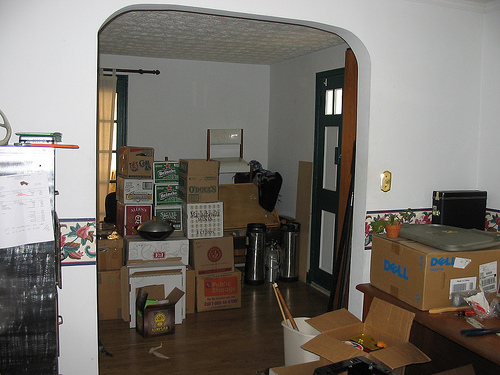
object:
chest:
[429, 188, 488, 232]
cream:
[277, 316, 323, 368]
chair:
[203, 127, 252, 174]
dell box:
[366, 232, 498, 313]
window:
[96, 151, 118, 184]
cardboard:
[114, 147, 130, 180]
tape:
[146, 340, 169, 361]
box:
[124, 234, 191, 266]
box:
[177, 158, 219, 204]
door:
[305, 66, 359, 293]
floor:
[96, 276, 361, 375]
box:
[114, 146, 156, 181]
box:
[185, 200, 227, 241]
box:
[193, 270, 245, 314]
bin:
[278, 315, 324, 369]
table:
[353, 280, 500, 375]